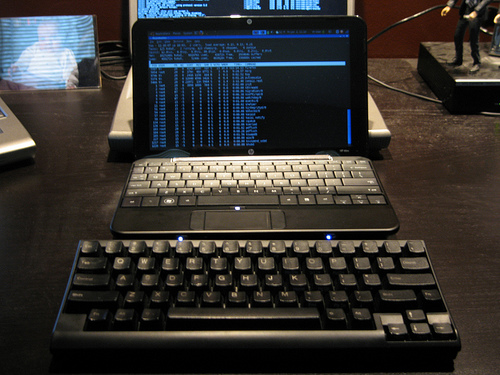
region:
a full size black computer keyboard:
[50, 233, 456, 368]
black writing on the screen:
[152, 35, 274, 148]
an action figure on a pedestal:
[436, 3, 494, 75]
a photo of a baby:
[7, 18, 107, 94]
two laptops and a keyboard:
[62, 3, 427, 361]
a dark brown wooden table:
[413, 129, 468, 214]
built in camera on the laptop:
[241, 14, 261, 29]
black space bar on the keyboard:
[168, 306, 325, 336]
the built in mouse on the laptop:
[201, 209, 276, 236]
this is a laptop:
[118, 20, 373, 235]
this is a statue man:
[450, 0, 480, 72]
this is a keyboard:
[130, 160, 360, 200]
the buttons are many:
[75, 240, 430, 320]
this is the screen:
[145, 32, 351, 147]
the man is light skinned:
[466, 10, 471, 15]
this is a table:
[415, 131, 490, 226]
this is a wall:
[371, 5, 386, 15]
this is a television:
[1, 16, 100, 88]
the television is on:
[3, 20, 94, 88]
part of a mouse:
[240, 214, 256, 222]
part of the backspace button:
[273, 312, 307, 327]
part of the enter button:
[392, 273, 422, 283]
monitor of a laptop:
[231, 102, 294, 142]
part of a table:
[36, 167, 68, 210]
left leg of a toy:
[468, 38, 480, 54]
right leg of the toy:
[452, 37, 468, 53]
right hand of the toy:
[439, 1, 451, 18]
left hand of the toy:
[464, 7, 476, 32]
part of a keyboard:
[235, 140, 381, 225]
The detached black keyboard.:
[73, 238, 453, 350]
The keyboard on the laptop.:
[127, 153, 384, 209]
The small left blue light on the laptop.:
[173, 234, 188, 241]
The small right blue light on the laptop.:
[321, 233, 338, 239]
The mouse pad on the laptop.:
[191, 207, 287, 229]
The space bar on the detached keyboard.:
[166, 302, 320, 324]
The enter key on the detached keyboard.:
[388, 268, 435, 285]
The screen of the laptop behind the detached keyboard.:
[148, 32, 354, 151]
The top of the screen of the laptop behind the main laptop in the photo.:
[135, 4, 349, 15]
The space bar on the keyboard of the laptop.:
[195, 194, 279, 204]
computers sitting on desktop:
[68, 2, 480, 360]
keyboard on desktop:
[53, 232, 461, 363]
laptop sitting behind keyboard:
[118, 6, 405, 234]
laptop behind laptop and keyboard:
[118, 5, 406, 148]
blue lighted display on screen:
[148, 29, 348, 153]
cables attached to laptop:
[362, 8, 465, 125]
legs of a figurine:
[430, 8, 493, 88]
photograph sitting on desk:
[8, 18, 100, 83]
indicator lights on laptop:
[173, 218, 352, 244]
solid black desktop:
[16, 47, 491, 338]